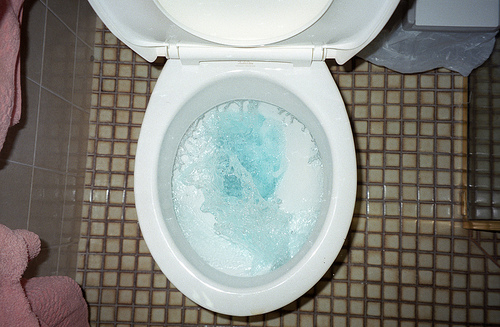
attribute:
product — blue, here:
[179, 104, 297, 269]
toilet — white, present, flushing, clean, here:
[88, 0, 407, 317]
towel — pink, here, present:
[0, 1, 31, 151]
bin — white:
[405, 1, 500, 34]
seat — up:
[88, 0, 404, 67]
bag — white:
[358, 14, 499, 77]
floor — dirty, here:
[73, 14, 499, 326]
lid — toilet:
[156, 0, 332, 46]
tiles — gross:
[75, 14, 500, 326]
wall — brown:
[1, 2, 98, 280]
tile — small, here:
[101, 60, 118, 79]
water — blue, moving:
[173, 98, 329, 281]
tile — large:
[41, 6, 75, 107]